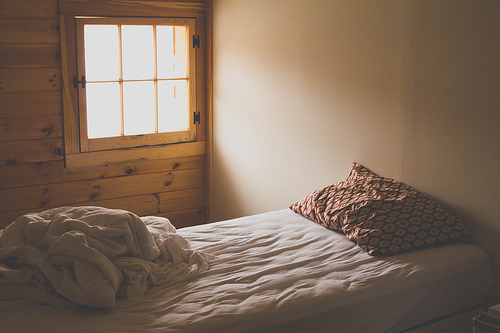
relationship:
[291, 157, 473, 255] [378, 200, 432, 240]
pillow has print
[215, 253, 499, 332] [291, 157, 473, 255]
bed has pillow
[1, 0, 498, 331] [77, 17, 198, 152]
bedroom has window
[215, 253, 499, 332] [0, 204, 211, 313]
bed has sheets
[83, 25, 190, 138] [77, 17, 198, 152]
six panels make window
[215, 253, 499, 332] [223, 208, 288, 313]
bed has fitted sheet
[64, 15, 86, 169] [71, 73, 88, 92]
left side has a middle clasp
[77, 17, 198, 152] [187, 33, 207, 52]
window frame has metal hinges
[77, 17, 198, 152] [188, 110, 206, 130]
window frame has bottom frame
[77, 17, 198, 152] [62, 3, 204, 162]
window has square shape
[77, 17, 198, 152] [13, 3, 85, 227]
window above wall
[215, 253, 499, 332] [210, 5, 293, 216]
bed next to beige wall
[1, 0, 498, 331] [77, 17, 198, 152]
room has window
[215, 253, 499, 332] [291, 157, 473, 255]
bed has a pillow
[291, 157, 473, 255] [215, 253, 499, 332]
pillow on bed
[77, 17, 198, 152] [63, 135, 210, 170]
window above wood sill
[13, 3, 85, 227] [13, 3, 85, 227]
wall has wall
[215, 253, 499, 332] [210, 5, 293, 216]
bed is in front of white wall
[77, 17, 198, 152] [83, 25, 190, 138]
window has six panes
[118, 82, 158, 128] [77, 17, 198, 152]
pane in window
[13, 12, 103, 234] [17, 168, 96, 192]
wall made of wood